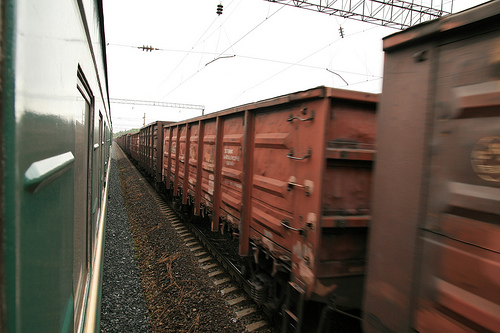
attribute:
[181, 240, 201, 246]
crosstie — wooden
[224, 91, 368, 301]
cargo — with rust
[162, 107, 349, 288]
goods carrier —  red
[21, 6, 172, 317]
train — green color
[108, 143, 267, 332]
rails — wooden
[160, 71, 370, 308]
cargo freight —  red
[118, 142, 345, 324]
tracks —  railroad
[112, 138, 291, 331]
track — brown color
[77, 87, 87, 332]
window — square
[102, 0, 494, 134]
sky — clear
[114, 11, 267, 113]
power lines —  a bunch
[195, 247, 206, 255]
crosstie — wooden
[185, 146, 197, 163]
circle — white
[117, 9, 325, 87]
sky — light grey,  overcast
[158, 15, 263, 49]
sky — white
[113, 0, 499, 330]
train — metal, red,  long,  for cargo 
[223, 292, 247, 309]
crosstie — wooden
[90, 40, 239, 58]
cords — for Power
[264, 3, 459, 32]
rods —  grey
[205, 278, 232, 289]
crosstie — wooden